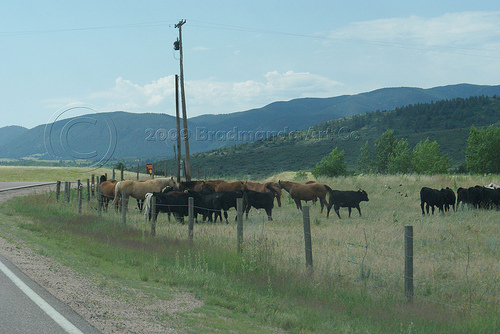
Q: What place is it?
A: It is a pasture.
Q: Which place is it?
A: It is a pasture.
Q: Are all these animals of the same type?
A: No, there are both horses and cows.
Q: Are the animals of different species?
A: Yes, they are horses and cows.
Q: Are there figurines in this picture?
A: No, there are no figurines.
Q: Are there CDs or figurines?
A: No, there are no figurines or cds.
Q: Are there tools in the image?
A: No, there are no tools.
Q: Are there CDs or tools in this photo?
A: No, there are no tools or cds.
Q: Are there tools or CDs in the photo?
A: No, there are no tools or cds.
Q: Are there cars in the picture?
A: No, there are no cars.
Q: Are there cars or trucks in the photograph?
A: No, there are no cars or trucks.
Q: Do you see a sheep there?
A: No, there is no sheep.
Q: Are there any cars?
A: No, there are no cars.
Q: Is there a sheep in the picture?
A: No, there is no sheep.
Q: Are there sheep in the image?
A: No, there are no sheep.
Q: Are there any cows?
A: Yes, there is a cow.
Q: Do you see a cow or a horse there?
A: Yes, there is a cow.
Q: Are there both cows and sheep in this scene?
A: No, there is a cow but no sheep.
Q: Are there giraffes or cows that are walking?
A: Yes, the cow is walking.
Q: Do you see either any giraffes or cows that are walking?
A: Yes, the cow is walking.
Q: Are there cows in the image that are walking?
A: Yes, there is a cow that is walking.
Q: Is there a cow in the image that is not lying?
A: Yes, there is a cow that is walking.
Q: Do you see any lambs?
A: No, there are no lambs.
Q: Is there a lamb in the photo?
A: No, there are no lambs.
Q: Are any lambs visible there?
A: No, there are no lambs.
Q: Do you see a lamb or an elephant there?
A: No, there are no lambs or elephants.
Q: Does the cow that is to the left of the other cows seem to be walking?
A: Yes, the cow is walking.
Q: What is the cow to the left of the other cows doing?
A: The cow is walking.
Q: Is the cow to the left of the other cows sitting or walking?
A: The cow is walking.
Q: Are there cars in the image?
A: No, there are no cars.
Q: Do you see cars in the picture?
A: No, there are no cars.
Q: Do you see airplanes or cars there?
A: No, there are no cars or airplanes.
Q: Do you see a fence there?
A: Yes, there is a fence.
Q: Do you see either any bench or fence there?
A: Yes, there is a fence.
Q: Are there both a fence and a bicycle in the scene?
A: No, there is a fence but no bicycles.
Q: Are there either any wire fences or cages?
A: Yes, there is a wire fence.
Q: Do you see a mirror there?
A: No, there are no mirrors.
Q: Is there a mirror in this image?
A: No, there are no mirrors.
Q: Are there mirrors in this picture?
A: No, there are no mirrors.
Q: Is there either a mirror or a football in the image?
A: No, there are no mirrors or footballs.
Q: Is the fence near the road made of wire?
A: Yes, the fence is made of wire.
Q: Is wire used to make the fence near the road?
A: Yes, the fence is made of wire.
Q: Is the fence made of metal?
A: No, the fence is made of wire.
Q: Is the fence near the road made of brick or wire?
A: The fence is made of wire.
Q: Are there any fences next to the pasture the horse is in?
A: Yes, there is a fence next to the pasture.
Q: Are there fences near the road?
A: Yes, there is a fence near the road.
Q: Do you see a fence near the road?
A: Yes, there is a fence near the road.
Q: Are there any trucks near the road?
A: No, there is a fence near the road.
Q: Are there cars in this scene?
A: No, there are no cars.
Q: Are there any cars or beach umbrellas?
A: No, there are no cars or beach umbrellas.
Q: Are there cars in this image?
A: No, there are no cars.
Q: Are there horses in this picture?
A: Yes, there is a horse.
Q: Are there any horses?
A: Yes, there is a horse.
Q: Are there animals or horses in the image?
A: Yes, there is a horse.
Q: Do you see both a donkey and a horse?
A: No, there is a horse but no donkeys.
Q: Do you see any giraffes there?
A: No, there are no giraffes.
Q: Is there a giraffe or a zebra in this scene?
A: No, there are no giraffes or zebras.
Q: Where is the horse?
A: The horse is in the pasture.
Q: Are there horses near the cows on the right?
A: Yes, there is a horse near the cows.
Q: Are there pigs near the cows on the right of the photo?
A: No, there is a horse near the cows.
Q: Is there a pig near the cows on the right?
A: No, there is a horse near the cows.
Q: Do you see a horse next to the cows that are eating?
A: Yes, there is a horse next to the cows.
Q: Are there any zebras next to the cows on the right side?
A: No, there is a horse next to the cows.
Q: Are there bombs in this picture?
A: No, there are no bombs.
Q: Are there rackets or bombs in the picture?
A: No, there are no bombs or rackets.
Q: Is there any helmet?
A: No, there are no helmets.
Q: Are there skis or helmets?
A: No, there are no helmets or skis.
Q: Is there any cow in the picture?
A: Yes, there are cows.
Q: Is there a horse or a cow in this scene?
A: Yes, there are cows.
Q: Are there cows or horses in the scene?
A: Yes, there are cows.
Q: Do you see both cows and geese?
A: No, there are cows but no geese.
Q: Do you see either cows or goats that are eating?
A: Yes, the cows are eating.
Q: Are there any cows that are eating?
A: Yes, there are cows that are eating.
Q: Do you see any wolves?
A: No, there are no wolves.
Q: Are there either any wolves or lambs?
A: No, there are no wolves or lambs.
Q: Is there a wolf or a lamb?
A: No, there are no wolves or lambs.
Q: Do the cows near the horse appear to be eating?
A: Yes, the cows are eating.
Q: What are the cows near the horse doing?
A: The cows are eating.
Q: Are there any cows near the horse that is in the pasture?
A: Yes, there are cows near the horse.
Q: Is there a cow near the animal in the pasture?
A: Yes, there are cows near the horse.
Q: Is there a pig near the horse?
A: No, there are cows near the horse.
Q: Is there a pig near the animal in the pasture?
A: No, there are cows near the horse.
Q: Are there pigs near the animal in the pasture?
A: No, there are cows near the horse.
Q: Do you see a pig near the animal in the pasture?
A: No, there are cows near the horse.